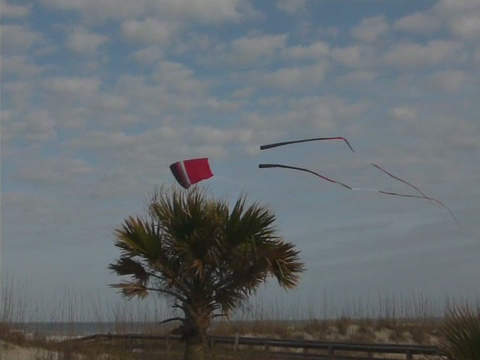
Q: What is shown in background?
A: Water.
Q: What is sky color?
A: Blue.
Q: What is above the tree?
A: A kite.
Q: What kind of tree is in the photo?
A: Palm tree.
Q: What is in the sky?
A: Clouds.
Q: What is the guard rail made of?
A: Metal.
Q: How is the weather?
A: Cloudy.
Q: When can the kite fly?
A: When the wind blows.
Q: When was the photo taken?
A: During the daytime.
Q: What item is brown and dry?
A: Grass.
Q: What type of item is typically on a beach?
A: Sand.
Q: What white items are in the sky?
A: Clouds.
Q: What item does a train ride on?
A: A track.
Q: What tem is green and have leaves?
A: A palm tree.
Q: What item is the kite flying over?
A: A palm tree.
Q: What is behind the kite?
A: Kite tails.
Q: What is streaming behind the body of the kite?
A: Two long, colorful tails.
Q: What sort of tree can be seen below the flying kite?
A: A palm tree.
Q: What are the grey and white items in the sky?
A: Clouds.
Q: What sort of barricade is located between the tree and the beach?
A: A metal guard rail.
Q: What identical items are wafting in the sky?
A: A pair of kite tails.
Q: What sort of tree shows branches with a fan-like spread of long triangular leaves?
A: A palm tree.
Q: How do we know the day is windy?
A: Two kite tails are wafting, high in the sky.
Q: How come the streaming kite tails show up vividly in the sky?
A: They are brightly colored, black, white and red.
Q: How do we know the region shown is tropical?
A: The lone tree on the beach is a palm tree.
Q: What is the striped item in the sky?
A: A kite.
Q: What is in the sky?
A: Clouds.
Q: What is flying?
A: Kite.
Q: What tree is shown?
A: Palm.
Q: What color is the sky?
A: Blue.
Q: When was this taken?
A: Daytime.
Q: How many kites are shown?
A: 1.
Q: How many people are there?
A: 0.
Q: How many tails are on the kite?
A: 2.